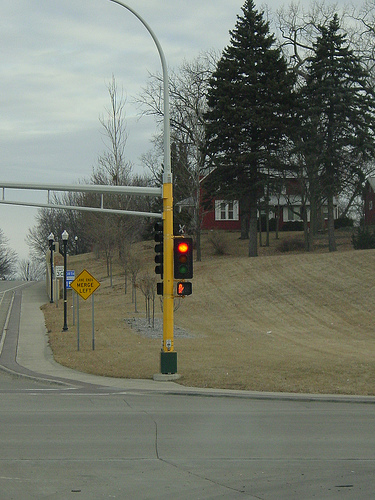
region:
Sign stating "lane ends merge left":
[68, 270, 101, 301]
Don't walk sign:
[175, 282, 191, 295]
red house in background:
[192, 170, 344, 231]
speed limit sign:
[52, 262, 65, 280]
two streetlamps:
[42, 220, 71, 331]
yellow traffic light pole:
[161, 182, 176, 357]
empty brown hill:
[223, 253, 369, 357]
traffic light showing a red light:
[170, 235, 196, 283]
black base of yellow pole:
[153, 350, 180, 375]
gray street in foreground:
[4, 400, 372, 495]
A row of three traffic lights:
[176, 236, 193, 279]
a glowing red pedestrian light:
[177, 282, 189, 292]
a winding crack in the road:
[111, 392, 227, 497]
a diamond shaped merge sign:
[70, 266, 101, 301]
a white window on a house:
[211, 198, 239, 223]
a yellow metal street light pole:
[157, 185, 180, 381]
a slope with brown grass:
[236, 263, 342, 366]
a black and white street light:
[57, 228, 70, 335]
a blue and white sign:
[65, 267, 74, 289]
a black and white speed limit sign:
[54, 264, 66, 277]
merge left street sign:
[69, 270, 105, 360]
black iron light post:
[60, 230, 70, 333]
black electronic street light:
[175, 234, 191, 280]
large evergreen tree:
[204, 0, 302, 260]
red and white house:
[196, 161, 339, 229]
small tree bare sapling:
[139, 270, 158, 330]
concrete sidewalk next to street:
[15, 274, 60, 373]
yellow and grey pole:
[147, 98, 179, 373]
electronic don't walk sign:
[175, 282, 190, 294]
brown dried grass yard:
[194, 260, 374, 385]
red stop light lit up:
[167, 235, 199, 280]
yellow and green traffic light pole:
[157, 192, 180, 380]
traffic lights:
[140, 217, 201, 298]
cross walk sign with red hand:
[171, 281, 194, 301]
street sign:
[66, 268, 97, 357]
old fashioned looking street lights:
[35, 223, 70, 336]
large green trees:
[190, 69, 296, 248]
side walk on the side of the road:
[13, 272, 52, 385]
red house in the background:
[199, 162, 301, 236]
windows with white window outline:
[213, 196, 244, 225]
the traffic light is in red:
[121, 178, 233, 319]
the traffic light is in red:
[124, 207, 189, 274]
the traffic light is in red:
[132, 244, 220, 333]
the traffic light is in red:
[144, 250, 236, 374]